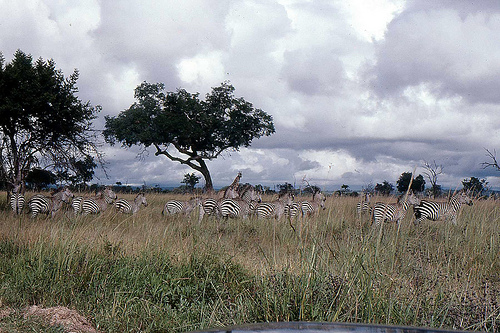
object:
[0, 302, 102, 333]
rocks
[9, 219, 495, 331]
grasses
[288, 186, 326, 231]
zebra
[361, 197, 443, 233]
zebra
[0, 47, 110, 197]
tree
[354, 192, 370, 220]
zebra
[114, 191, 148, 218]
white zebra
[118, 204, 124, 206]
black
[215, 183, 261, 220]
zebra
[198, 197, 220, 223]
zebra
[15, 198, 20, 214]
tail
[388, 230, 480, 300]
ground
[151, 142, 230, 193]
trunk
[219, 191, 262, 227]
zebra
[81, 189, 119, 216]
zebra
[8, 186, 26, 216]
zebra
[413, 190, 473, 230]
zebra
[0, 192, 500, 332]
field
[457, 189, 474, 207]
head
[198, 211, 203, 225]
leg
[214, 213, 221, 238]
leg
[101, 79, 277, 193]
tree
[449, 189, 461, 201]
short mane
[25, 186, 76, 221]
zebra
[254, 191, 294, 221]
zebra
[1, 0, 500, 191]
sky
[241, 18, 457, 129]
clouds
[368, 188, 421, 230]
baby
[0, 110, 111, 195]
branches